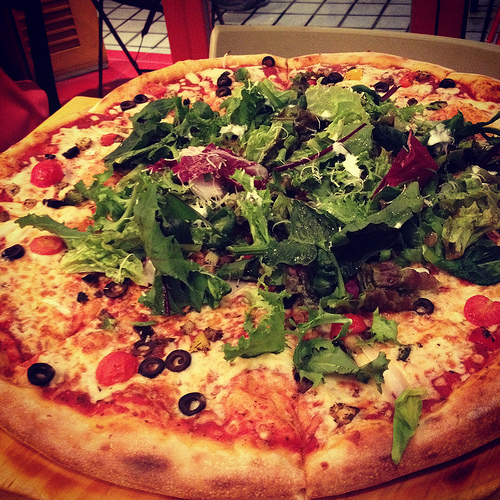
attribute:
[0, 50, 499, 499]
pizza — round, cooked, large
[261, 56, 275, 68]
olive — black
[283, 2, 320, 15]
tile — square, white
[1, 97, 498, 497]
board — brown, wood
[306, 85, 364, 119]
leaf — green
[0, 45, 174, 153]
rug — red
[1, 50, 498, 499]
crust — brown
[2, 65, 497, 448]
cheese — grated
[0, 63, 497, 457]
sauce — red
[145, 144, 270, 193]
salad — purple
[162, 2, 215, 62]
column — red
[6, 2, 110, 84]
door — wooden, narrow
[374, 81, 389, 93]
olive — black